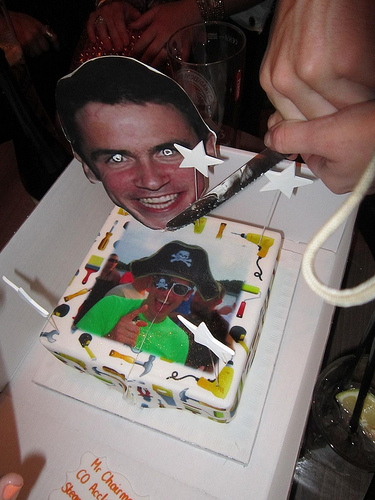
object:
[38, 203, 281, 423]
cake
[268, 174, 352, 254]
board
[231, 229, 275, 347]
tools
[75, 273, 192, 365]
man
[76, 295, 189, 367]
shirt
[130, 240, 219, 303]
hat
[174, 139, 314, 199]
stars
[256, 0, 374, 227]
person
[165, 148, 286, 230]
knife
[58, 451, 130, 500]
writing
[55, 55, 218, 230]
cardboard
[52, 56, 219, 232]
head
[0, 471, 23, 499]
finger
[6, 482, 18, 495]
polish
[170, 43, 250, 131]
glass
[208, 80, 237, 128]
beer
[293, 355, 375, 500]
glass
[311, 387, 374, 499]
drink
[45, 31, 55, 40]
ring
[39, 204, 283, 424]
picture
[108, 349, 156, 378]
hammer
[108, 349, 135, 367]
handle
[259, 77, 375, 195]
hands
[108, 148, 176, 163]
eyes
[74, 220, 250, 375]
photo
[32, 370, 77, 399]
paper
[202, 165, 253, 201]
frosting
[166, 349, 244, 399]
drill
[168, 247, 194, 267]
demonic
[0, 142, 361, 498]
box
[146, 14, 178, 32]
part